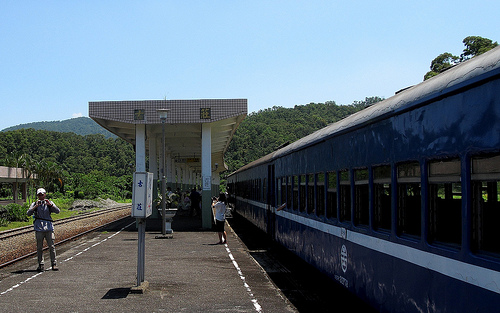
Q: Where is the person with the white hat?
A: On the left side of the platform.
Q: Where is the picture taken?
A: Train stop.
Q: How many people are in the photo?
A: Two.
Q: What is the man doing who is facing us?
A: Taking a picture.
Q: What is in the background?
A: Mountains.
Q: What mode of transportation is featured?
A: Train.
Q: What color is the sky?
A: Blue.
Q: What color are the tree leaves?
A: Green.